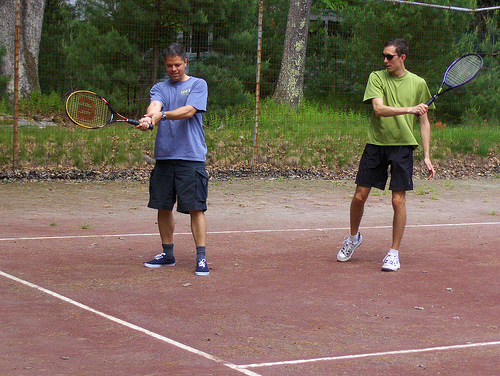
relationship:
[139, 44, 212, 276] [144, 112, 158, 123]
man holding wrist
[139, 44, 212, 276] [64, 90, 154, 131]
man holding tennis racket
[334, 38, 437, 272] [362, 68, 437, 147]
man wearing t-shirt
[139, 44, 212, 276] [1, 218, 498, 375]
man standing on tennis court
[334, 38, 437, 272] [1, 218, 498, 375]
man standing on tennis court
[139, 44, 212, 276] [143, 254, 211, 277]
man wearing tennis shoes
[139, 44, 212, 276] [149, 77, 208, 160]
man wearing shirt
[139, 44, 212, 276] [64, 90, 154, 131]
man swinging tennis racket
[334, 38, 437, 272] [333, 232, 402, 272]
man wearing sneakers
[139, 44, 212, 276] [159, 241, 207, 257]
man wearing socks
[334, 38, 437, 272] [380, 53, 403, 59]
man wearing sunglasses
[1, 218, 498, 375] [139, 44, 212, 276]
tennis court under man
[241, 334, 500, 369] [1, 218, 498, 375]
line on tennis court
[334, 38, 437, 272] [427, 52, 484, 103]
man holding tennis racket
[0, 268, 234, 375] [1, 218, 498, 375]
line on tennis court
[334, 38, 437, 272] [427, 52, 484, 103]
man swinging tennis racket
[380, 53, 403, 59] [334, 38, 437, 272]
sunglasses on man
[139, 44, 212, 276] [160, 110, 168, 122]
man wearing watch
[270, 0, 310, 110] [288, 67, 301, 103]
tree has moss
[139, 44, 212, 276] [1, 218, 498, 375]
man on tennis court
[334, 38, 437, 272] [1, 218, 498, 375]
man on tennis court